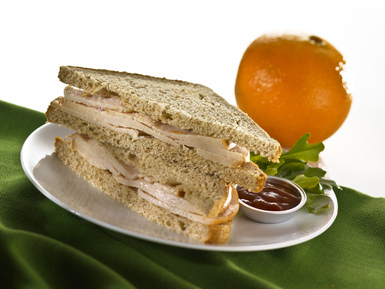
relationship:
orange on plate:
[264, 30, 346, 139] [276, 228, 302, 250]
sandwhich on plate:
[69, 62, 228, 225] [276, 228, 302, 250]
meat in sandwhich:
[106, 103, 139, 133] [69, 62, 228, 225]